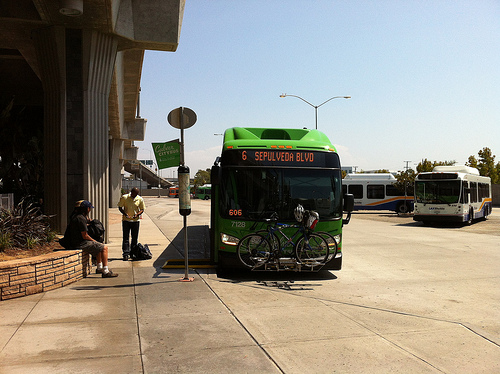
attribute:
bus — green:
[187, 119, 362, 290]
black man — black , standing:
[120, 184, 144, 260]